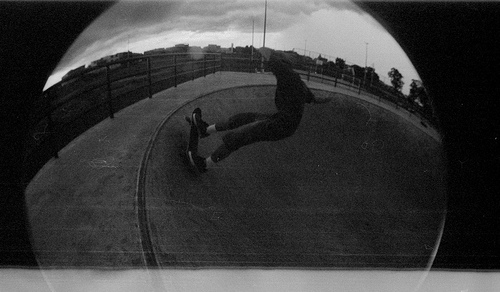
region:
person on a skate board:
[172, 43, 339, 195]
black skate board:
[174, 98, 219, 185]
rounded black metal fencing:
[38, 43, 413, 154]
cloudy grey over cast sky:
[41, 5, 428, 99]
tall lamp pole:
[255, 1, 277, 62]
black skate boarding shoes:
[185, 101, 213, 179]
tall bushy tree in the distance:
[381, 62, 409, 104]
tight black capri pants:
[210, 106, 305, 166]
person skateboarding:
[175, 37, 348, 184]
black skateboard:
[183, 100, 215, 181]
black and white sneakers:
[183, 106, 214, 181]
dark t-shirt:
[259, 46, 319, 143]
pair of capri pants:
[218, 106, 297, 160]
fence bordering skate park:
[3, 50, 450, 204]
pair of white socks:
[199, 118, 217, 172]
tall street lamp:
[355, 34, 375, 78]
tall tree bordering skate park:
[380, 58, 407, 115]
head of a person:
[273, 42, 300, 73]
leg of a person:
[205, 94, 275, 130]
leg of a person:
[205, 140, 253, 164]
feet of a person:
[190, 105, 205, 129]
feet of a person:
[185, 145, 216, 170]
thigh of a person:
[245, 104, 275, 122]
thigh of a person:
[236, 124, 276, 145]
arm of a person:
[300, 82, 342, 115]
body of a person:
[262, 57, 337, 122]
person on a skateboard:
[140, 16, 351, 201]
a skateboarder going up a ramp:
[169, 27, 336, 199]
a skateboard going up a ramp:
[171, 96, 218, 181]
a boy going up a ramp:
[138, 40, 335, 185]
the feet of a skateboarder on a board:
[175, 100, 216, 184]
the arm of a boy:
[307, 80, 340, 113]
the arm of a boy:
[245, 35, 272, 75]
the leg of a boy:
[204, 125, 278, 181]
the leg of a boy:
[213, 106, 275, 128]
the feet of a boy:
[175, 96, 216, 184]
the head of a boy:
[266, 44, 293, 76]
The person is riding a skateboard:
[151, 53, 328, 182]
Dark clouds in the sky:
[35, 2, 440, 91]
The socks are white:
[187, 110, 235, 185]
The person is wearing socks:
[177, 45, 321, 187]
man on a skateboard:
[165, 33, 346, 180]